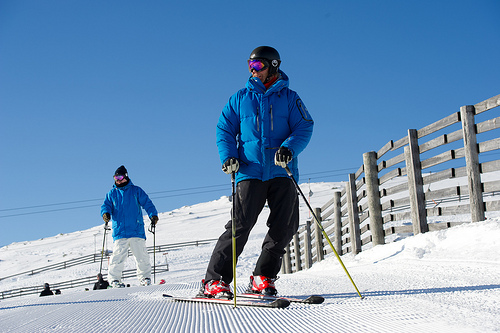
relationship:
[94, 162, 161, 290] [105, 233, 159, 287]
person wearing pants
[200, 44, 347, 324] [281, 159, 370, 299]
person has right ski pole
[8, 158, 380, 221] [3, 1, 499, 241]
power lines in sky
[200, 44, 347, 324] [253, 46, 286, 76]
person wearing a helmet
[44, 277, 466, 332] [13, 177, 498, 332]
tracks in snow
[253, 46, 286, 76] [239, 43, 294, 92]
helmet on persons head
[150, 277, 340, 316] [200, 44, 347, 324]
skis on person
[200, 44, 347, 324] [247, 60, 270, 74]
person wearing goggles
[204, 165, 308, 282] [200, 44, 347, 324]
pants on person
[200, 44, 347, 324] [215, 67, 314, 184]
person wears a coat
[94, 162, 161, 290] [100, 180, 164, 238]
person wears a jacket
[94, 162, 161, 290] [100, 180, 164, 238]
person wears jacket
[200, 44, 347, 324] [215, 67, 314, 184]
person wears coat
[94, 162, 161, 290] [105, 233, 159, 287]
person wears pants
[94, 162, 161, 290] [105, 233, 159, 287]
person wearing white pants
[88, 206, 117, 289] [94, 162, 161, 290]
left ski pole of a person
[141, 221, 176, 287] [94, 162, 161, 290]
right ski pole of a person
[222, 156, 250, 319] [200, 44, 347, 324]
left ski pole of person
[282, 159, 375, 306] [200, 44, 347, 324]
right ski pole of person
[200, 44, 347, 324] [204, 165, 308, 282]
person wearing pants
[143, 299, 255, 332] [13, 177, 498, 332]
lines in snow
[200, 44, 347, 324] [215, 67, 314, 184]
person wearing blue coat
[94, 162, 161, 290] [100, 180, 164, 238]
person wearing blue jacket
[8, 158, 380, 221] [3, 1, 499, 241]
wires in sky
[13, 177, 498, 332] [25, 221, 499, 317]
snow on ground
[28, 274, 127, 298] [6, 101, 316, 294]
people in background